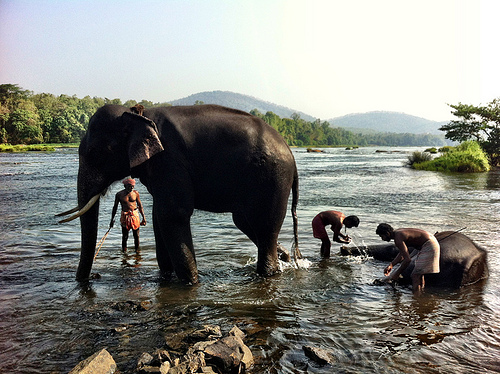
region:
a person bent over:
[313, 210, 358, 255]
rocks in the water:
[76, 315, 247, 372]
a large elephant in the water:
[58, 98, 302, 282]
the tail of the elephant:
[293, 169, 300, 262]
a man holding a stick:
[111, 184, 147, 253]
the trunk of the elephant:
[71, 165, 98, 283]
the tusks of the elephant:
[57, 195, 101, 224]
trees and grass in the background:
[418, 105, 496, 175]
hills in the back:
[179, 77, 488, 145]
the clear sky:
[11, 55, 486, 78]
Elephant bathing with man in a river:
[57, 104, 302, 284]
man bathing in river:
[311, 208, 360, 260]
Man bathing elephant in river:
[339, 222, 489, 305]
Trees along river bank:
[395, 95, 498, 175]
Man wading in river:
[104, 177, 146, 252]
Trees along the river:
[0, 83, 75, 154]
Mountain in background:
[326, 107, 446, 145]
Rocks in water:
[66, 318, 330, 373]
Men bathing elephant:
[311, 205, 498, 302]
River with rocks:
[301, 147, 498, 207]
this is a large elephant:
[115, 55, 278, 217]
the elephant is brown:
[126, 141, 177, 183]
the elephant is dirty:
[136, 58, 316, 331]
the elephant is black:
[130, 145, 330, 207]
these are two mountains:
[215, 45, 401, 155]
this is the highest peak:
[155, 76, 320, 117]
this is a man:
[323, 215, 378, 280]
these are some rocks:
[165, 305, 172, 312]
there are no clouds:
[339, 82, 394, 132]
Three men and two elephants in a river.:
[54, 103, 489, 293]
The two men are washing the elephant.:
[310, 209, 489, 291]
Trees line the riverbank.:
[1, 82, 446, 149]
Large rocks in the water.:
[70, 323, 255, 372]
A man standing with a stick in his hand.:
[92, 178, 147, 263]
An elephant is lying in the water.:
[339, 229, 489, 288]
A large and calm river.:
[2, 145, 498, 372]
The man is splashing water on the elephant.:
[310, 209, 370, 265]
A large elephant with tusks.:
[55, 103, 300, 282]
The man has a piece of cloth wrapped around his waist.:
[414, 236, 440, 273]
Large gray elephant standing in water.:
[55, 101, 305, 296]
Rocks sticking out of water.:
[67, 318, 262, 372]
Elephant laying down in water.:
[339, 230, 489, 293]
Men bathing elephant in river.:
[310, 205, 491, 299]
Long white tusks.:
[49, 193, 106, 228]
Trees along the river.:
[2, 82, 358, 149]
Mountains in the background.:
[170, 82, 459, 144]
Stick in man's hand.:
[95, 205, 120, 264]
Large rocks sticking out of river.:
[303, 139, 441, 161]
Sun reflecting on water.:
[300, 143, 431, 220]